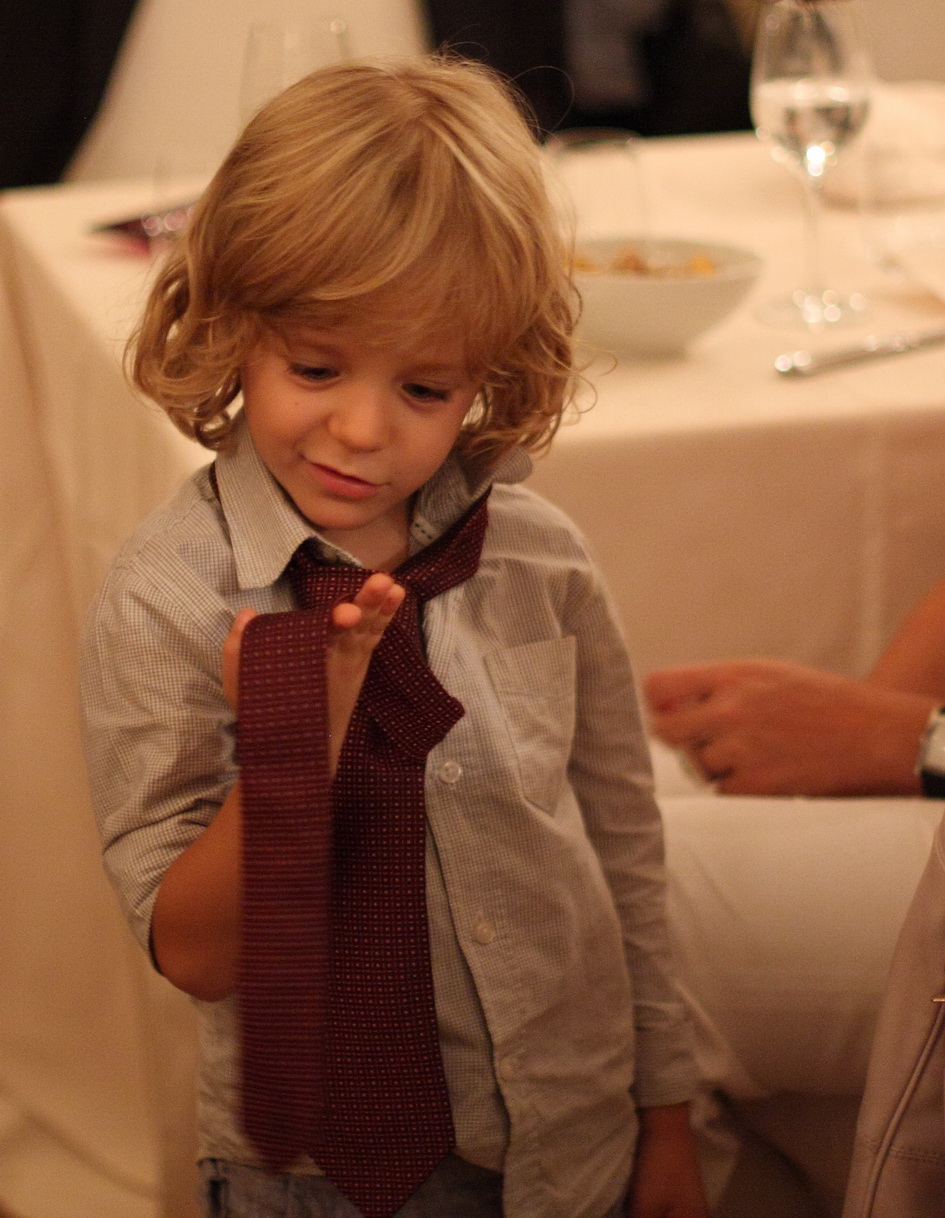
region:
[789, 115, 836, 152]
the liquid is clear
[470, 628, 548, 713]
the shirt is white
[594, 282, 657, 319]
the bowl is white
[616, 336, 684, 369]
the bowl is on the table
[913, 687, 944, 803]
the person is wearing a watch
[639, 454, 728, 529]
the tablecloth is a cream color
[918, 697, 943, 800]
watch on the wrist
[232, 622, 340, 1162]
red tie on the shirt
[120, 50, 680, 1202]
boy holding a tie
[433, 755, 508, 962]
buttons on the shirt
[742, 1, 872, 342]
wineglass on the table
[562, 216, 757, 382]
bowl of food on the table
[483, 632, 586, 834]
pocket on the shirt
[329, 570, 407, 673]
fingers on the han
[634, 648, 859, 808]
hand of a person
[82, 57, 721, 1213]
Little boy in the forefront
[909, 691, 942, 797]
Watch on the wrist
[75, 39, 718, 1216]
Little boy wearing a tie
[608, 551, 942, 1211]
White pants on the person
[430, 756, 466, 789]
Button on the shirt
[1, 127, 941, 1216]
White table cloth on the table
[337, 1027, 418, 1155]
a red tie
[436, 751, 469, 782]
a clear button on the shirt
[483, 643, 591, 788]
a pocket on the shirt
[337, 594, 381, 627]
the childs fingers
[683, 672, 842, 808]
a persons hand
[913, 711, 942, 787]
a watch on the wrist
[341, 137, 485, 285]
the childs hair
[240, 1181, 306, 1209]
child is wearing jeans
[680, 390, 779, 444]
the table cloth is white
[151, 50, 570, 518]
the boy has long blond hair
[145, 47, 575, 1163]
the boy is wearing a neck tie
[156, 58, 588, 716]
the boy is holding his tie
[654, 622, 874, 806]
the hand and fingers of a person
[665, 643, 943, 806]
the person is wearing a black and silver watch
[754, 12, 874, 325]
the glass has water in it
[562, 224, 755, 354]
the white bowl contains food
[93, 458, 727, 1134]
the shirt has long sleeves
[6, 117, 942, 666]
the table has a white table cloth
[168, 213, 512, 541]
the little boy is smiling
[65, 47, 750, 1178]
A boy with blonde hair.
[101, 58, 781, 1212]
A boy wearing a tie.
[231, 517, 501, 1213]
A red neck tie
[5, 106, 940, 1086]
A white tablecloth on a table.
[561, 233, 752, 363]
A round white bowl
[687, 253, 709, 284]
A piece of food.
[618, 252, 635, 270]
A piece of food.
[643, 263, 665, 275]
A piece of food.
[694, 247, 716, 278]
A piece of food.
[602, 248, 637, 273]
A piece of food.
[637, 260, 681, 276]
A piece of food.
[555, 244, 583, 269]
A piece of food.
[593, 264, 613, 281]
A piece of food.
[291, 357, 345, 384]
eye belongs to human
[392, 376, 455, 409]
eye belongs to human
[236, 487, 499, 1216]
red tie is worn by human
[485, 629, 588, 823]
pocket is attached to shirt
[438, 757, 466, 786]
button is attached to shirt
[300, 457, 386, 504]
mouth belongs to human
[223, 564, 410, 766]
hand belongs to human